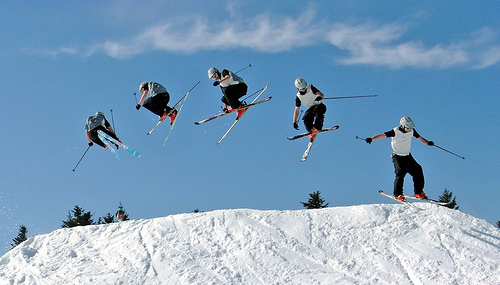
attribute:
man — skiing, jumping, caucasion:
[60, 90, 152, 194]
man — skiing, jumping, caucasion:
[120, 68, 200, 156]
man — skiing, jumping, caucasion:
[193, 55, 277, 152]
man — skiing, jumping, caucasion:
[273, 63, 357, 185]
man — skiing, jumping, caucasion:
[363, 100, 465, 220]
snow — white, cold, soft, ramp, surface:
[2, 197, 499, 285]